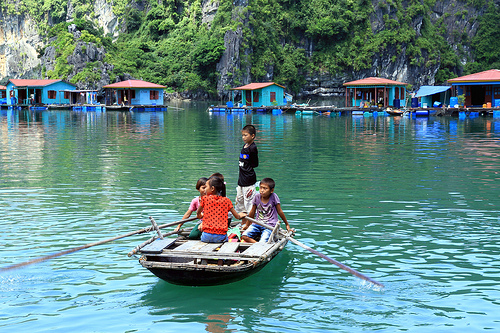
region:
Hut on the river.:
[226, 78, 284, 110]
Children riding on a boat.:
[125, 121, 291, 283]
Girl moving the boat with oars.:
[195, 170, 242, 240]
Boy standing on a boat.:
[235, 121, 257, 226]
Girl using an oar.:
[0, 212, 197, 267]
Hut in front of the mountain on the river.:
[100, 75, 160, 106]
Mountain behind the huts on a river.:
[0, 0, 495, 65]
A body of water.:
[5, 120, 180, 205]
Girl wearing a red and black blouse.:
[196, 195, 226, 231]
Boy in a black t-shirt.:
[237, 142, 257, 182]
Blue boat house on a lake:
[218, 80, 298, 112]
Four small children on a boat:
[151, 119, 295, 284]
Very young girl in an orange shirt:
[197, 174, 239, 248]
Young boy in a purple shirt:
[244, 176, 284, 243]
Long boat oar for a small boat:
[235, 206, 391, 298]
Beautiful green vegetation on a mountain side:
[115, 8, 241, 73]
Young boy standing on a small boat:
[232, 123, 260, 216]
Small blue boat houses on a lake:
[1, 74, 172, 116]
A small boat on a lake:
[146, 213, 293, 285]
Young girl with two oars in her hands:
[167, 173, 262, 245]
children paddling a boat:
[104, 91, 359, 328]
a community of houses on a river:
[6, 72, 492, 132]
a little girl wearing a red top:
[199, 174, 238, 249]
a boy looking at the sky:
[240, 174, 288, 248]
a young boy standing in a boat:
[234, 120, 259, 209]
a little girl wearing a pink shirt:
[184, 180, 203, 220]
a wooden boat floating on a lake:
[120, 244, 252, 290]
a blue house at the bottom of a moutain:
[230, 82, 298, 109]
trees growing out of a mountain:
[161, 29, 231, 60]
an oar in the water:
[293, 238, 394, 293]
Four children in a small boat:
[177, 122, 288, 224]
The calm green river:
[315, 162, 477, 237]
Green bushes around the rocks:
[133, 5, 207, 72]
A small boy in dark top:
[236, 124, 260, 187]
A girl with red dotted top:
[196, 192, 235, 230]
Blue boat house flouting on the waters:
[107, 73, 172, 108]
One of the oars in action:
[301, 236, 380, 297]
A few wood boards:
[147, 240, 269, 259]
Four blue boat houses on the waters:
[4, 77, 413, 116]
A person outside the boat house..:
[21, 87, 39, 109]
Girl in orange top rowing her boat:
[183, 175, 241, 243]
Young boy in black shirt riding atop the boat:
[231, 123, 263, 221]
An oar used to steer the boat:
[235, 211, 397, 295]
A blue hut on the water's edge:
[107, 76, 176, 108]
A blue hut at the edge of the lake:
[215, 77, 303, 117]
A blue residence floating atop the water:
[3, 79, 80, 114]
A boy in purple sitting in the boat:
[233, 177, 298, 252]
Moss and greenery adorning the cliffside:
[8, 5, 485, 77]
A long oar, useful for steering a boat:
[1, 207, 206, 282]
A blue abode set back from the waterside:
[341, 69, 412, 116]